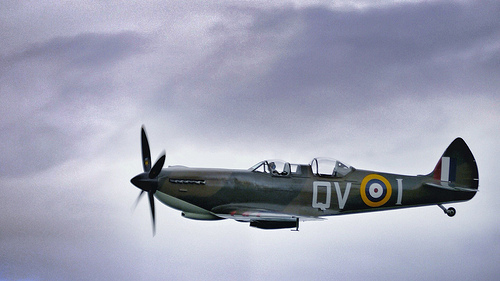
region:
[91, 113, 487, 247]
Plane flying in a cloudy sky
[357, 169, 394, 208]
Yellow bullseye on the side of a plane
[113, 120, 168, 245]
Large propeller helps the plane fly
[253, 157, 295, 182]
Pilot occupying the main cockpit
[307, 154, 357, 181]
Second cockpit is empty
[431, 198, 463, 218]
Back landing gear peaking from the bottom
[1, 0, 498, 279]
Dark cloudy sky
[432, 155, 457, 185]
Red white and blue stripes on the tail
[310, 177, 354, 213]
Large Letters Q and V painted on the side of the plane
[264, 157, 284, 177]
Pilot wearing head gear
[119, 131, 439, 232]
gray airplane in air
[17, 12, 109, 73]
white clouds in blue sky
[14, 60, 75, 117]
white clouds in blue sky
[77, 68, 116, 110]
white clouds in blue sky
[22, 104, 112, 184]
white clouds in blue sky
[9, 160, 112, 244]
white clouds in blue sky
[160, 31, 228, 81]
white clouds in blue sky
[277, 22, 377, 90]
white clouds in blue sky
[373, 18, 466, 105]
white clouds in blue sky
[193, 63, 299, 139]
white clouds in blue sky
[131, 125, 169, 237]
The propeller is four-bladed.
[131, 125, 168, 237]
The propeller is black.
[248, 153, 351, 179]
The airplane has two cockpits.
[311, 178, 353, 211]
The letters Q and V are on the plane.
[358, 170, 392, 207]
The roundel is of the British Royal Airforce.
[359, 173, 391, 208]
The roundel is yellow, blue, white, and red.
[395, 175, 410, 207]
The letter I is on the plane.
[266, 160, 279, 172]
A pilot is in the front cockpit.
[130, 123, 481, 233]
The airplane is dark green and olive drab.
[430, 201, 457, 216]
The rear landing wheel is under the tail.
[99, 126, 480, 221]
old style gray airplane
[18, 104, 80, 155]
white clouds in blue sky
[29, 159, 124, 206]
white clouds in blue sky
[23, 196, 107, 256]
white clouds in blue sky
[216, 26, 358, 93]
white clouds in blue sky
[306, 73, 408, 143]
white clouds in blue sky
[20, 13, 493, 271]
cloudy gray skies behind an airplane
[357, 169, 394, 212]
red, white, gray and yellow circles on a plane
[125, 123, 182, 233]
gray propeller of an airplane in flight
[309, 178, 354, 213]
white letters on the side of a gray airplane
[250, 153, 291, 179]
cockpit of airplane with glass cover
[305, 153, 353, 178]
glass cover over passenger seat on airplane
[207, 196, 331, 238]
left wing of a gray airplane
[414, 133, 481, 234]
tail of gray airplane with white rectangle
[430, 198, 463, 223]
gray and black rear wheel of airplane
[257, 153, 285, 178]
pilot of a gray airplane in flight